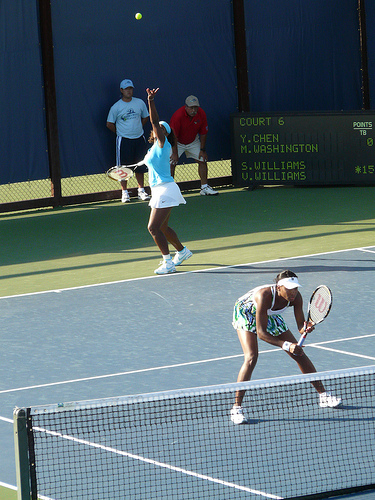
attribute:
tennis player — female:
[123, 86, 194, 274]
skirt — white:
[146, 178, 188, 206]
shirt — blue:
[140, 133, 175, 188]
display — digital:
[232, 115, 374, 185]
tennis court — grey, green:
[7, 237, 238, 384]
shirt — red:
[168, 107, 208, 145]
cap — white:
[183, 93, 202, 110]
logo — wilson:
[311, 294, 329, 316]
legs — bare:
[146, 204, 184, 253]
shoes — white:
[152, 247, 190, 276]